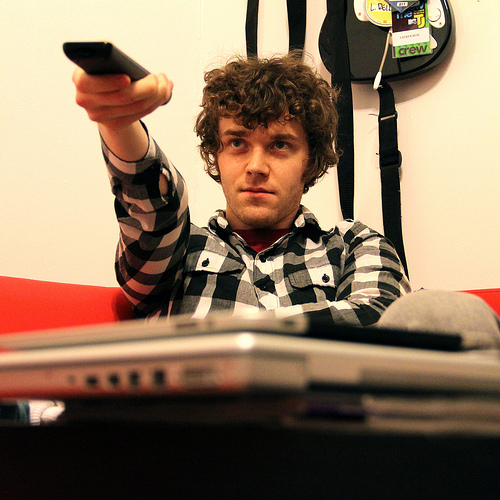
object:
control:
[57, 35, 175, 107]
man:
[69, 47, 500, 361]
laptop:
[3, 309, 499, 405]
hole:
[86, 372, 100, 389]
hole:
[107, 372, 121, 386]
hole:
[128, 368, 141, 389]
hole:
[151, 366, 167, 387]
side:
[3, 332, 247, 394]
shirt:
[96, 118, 412, 331]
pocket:
[167, 247, 246, 314]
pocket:
[285, 262, 344, 305]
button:
[201, 259, 210, 267]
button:
[321, 274, 330, 283]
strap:
[242, 1, 258, 61]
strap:
[285, 1, 308, 62]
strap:
[318, 0, 356, 220]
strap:
[377, 80, 410, 285]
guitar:
[316, 0, 457, 84]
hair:
[195, 48, 343, 195]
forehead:
[220, 108, 300, 130]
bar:
[372, 26, 393, 91]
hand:
[71, 68, 177, 133]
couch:
[0, 273, 500, 347]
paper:
[393, 41, 431, 59]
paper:
[392, 27, 430, 48]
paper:
[393, 1, 428, 36]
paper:
[363, 0, 395, 31]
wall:
[0, 0, 500, 288]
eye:
[227, 138, 249, 153]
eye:
[269, 140, 293, 153]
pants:
[374, 285, 500, 353]